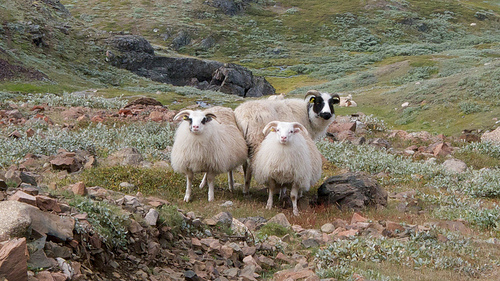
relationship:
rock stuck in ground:
[263, 210, 293, 234] [3, 79, 483, 276]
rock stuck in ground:
[144, 206, 161, 226] [3, 79, 483, 276]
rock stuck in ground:
[319, 220, 336, 235] [3, 79, 483, 276]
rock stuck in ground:
[116, 178, 136, 194] [3, 79, 483, 276]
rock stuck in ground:
[220, 196, 238, 206] [3, 79, 483, 276]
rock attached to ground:
[194, 255, 214, 275] [1, 0, 498, 278]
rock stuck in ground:
[142, 204, 162, 228] [137, 219, 174, 244]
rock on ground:
[317, 173, 387, 207] [238, 3, 355, 69]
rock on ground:
[317, 173, 387, 207] [0, 187, 485, 275]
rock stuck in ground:
[432, 140, 454, 160] [1, 0, 498, 278]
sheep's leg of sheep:
[290, 182, 298, 209] [251, 120, 320, 214]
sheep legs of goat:
[177, 167, 237, 201] [169, 105, 249, 202]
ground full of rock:
[1, 0, 498, 278] [317, 173, 387, 207]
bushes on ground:
[332, 131, 434, 186] [1, 0, 498, 278]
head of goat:
[306, 90, 343, 120] [232, 89, 340, 193]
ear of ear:
[306, 95, 322, 115] [308, 96, 316, 103]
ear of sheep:
[336, 92, 343, 109] [227, 90, 344, 170]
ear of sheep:
[294, 127, 299, 132] [251, 120, 320, 214]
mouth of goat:
[276, 136, 288, 147] [251, 120, 321, 216]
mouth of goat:
[189, 124, 204, 136] [169, 105, 249, 202]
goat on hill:
[232, 89, 342, 194] [4, 4, 498, 269]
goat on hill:
[252, 120, 321, 214] [4, 4, 498, 269]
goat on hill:
[171, 105, 246, 201] [4, 4, 498, 269]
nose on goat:
[187, 113, 200, 139] [127, 83, 271, 208]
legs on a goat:
[147, 159, 328, 244] [169, 105, 249, 202]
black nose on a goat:
[317, 110, 335, 121] [166, 102, 254, 206]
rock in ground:
[148, 107, 163, 121] [1, 0, 498, 278]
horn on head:
[304, 89, 320, 99] [306, 90, 343, 120]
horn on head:
[331, 92, 340, 99] [306, 90, 343, 120]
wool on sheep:
[176, 135, 245, 172] [102, 21, 417, 250]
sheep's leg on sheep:
[284, 172, 304, 217] [168, 75, 345, 227]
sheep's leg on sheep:
[260, 178, 277, 212] [168, 75, 345, 227]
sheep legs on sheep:
[207, 172, 215, 198] [168, 75, 345, 227]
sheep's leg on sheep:
[178, 170, 193, 200] [168, 75, 345, 227]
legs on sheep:
[206, 171, 215, 197] [167, 62, 362, 234]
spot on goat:
[290, 194, 297, 202] [251, 120, 321, 216]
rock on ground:
[0, 235, 29, 279] [0, 157, 497, 277]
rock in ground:
[317, 173, 387, 207] [304, 207, 498, 279]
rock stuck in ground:
[314, 165, 386, 216] [332, 7, 497, 276]